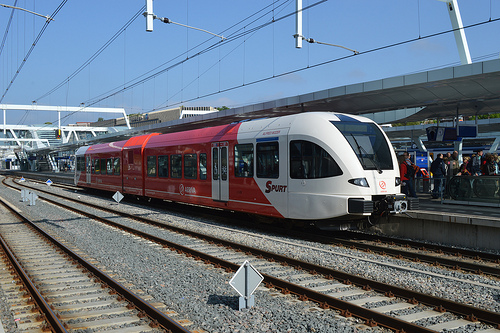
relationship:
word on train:
[263, 180, 287, 193] [72, 107, 404, 228]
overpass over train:
[1, 101, 135, 165] [82, 113, 399, 220]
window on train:
[284, 134, 344, 184] [22, 111, 406, 243]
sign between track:
[224, 258, 266, 312] [2, 195, 194, 330]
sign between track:
[224, 258, 266, 312] [1, 172, 498, 329]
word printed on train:
[261, 177, 288, 198] [72, 107, 404, 228]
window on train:
[338, 119, 393, 170] [72, 107, 404, 228]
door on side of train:
[209, 140, 229, 200] [72, 107, 404, 228]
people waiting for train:
[395, 144, 494, 204] [18, 112, 457, 242]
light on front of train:
[347, 176, 371, 187] [1, 112, 415, 233]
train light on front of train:
[395, 177, 401, 184] [1, 112, 415, 233]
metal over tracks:
[10, 96, 140, 134] [5, 171, 498, 331]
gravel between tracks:
[0, 182, 392, 331] [23, 168, 485, 322]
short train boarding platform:
[73, 111, 409, 232] [370, 194, 498, 267]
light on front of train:
[351, 176, 371, 195] [55, 117, 419, 257]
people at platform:
[395, 144, 499, 200] [408, 154, 478, 211]